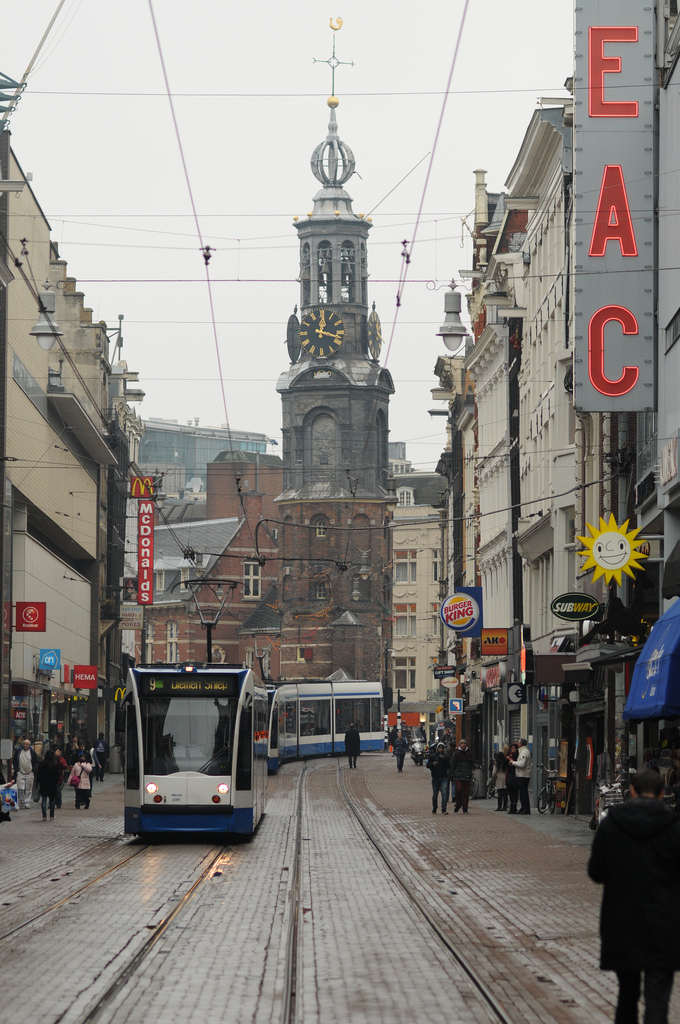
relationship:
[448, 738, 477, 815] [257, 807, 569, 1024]
man walking on road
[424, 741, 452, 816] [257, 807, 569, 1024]
woman walking on road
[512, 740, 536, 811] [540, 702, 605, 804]
man standing in front of store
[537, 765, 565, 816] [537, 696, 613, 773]
bike in front of store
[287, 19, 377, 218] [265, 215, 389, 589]
steeple on top of building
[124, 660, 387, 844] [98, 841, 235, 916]
street car on track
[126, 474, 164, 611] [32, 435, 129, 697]
sign attached to building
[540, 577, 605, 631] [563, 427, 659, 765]
sign attached to building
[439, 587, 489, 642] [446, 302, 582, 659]
sign attached to building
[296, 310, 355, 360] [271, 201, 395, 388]
clock on tower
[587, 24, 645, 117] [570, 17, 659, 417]
letter on a sign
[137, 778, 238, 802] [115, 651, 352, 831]
headlights are on a train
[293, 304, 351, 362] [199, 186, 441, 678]
clocks are on a building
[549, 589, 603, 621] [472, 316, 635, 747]
sign on a building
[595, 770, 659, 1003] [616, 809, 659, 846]
man wearing a coat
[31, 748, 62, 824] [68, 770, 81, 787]
person carrying a bag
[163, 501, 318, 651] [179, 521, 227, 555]
building has a roof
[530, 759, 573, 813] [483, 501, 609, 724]
bicycle leaning against a building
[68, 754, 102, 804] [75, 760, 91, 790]
woman wearing a coat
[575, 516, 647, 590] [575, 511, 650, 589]
sign has a smiling sign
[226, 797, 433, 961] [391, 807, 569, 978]
tracks are in road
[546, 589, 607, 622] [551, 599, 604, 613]
sign has letters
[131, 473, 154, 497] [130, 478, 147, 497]
symbol has golden arches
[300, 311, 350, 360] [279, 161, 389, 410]
clock on tower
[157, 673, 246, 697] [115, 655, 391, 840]
destination sign on streetcar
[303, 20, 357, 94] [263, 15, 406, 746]
cross on top of building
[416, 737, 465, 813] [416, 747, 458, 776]
person wearing jacket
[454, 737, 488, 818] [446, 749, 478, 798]
person wearing jacket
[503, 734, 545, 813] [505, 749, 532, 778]
person wearing jacket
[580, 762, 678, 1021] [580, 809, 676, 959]
person wearing jacket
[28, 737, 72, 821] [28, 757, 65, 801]
person wearing jacket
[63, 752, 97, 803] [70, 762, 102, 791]
person wearing jacket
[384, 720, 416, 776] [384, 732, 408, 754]
person wearing jacket